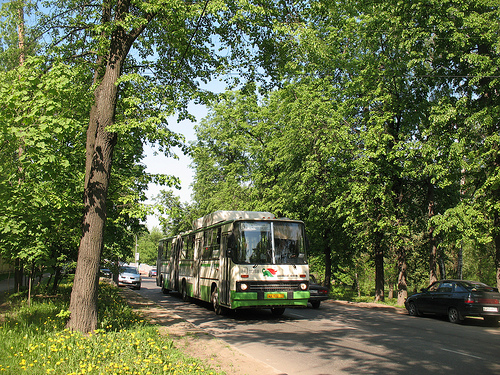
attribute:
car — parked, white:
[405, 277, 499, 320]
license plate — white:
[482, 306, 499, 315]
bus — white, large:
[152, 207, 314, 322]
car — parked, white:
[98, 258, 168, 313]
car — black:
[401, 277, 498, 329]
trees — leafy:
[161, 74, 456, 278]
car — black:
[400, 269, 498, 330]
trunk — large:
[41, 53, 152, 358]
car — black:
[400, 274, 498, 319]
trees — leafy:
[319, 2, 496, 305]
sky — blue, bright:
[186, 73, 223, 134]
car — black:
[403, 265, 489, 310]